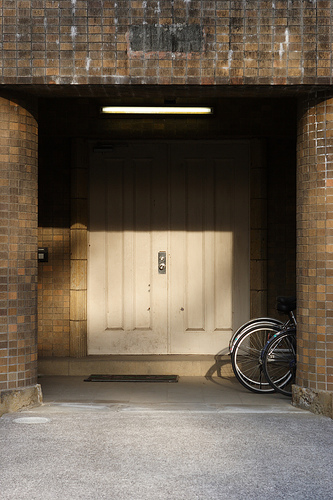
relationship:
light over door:
[101, 105, 212, 116] [87, 138, 252, 353]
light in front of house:
[101, 105, 212, 116] [18, 22, 321, 262]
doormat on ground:
[79, 367, 184, 395] [49, 370, 277, 434]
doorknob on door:
[158, 251, 166, 275] [85, 212, 255, 345]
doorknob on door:
[152, 263, 171, 276] [92, 145, 243, 346]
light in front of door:
[101, 103, 212, 115] [87, 138, 252, 353]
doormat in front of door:
[90, 372, 180, 383] [87, 138, 252, 353]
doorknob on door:
[158, 251, 166, 275] [80, 134, 262, 366]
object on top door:
[98, 120, 177, 131] [93, 147, 255, 328]